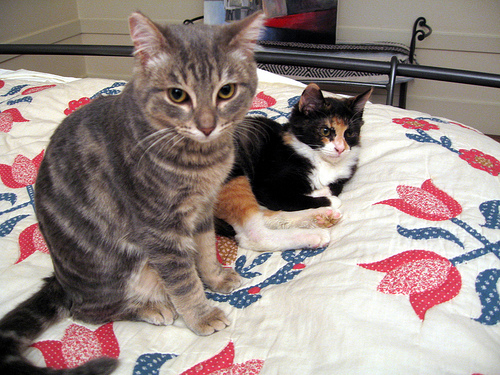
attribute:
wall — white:
[1, 3, 495, 129]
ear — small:
[124, 11, 169, 61]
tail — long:
[1, 274, 121, 375]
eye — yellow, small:
[162, 85, 191, 105]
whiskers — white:
[120, 117, 196, 174]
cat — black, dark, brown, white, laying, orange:
[212, 71, 374, 251]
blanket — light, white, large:
[2, 20, 499, 373]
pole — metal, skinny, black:
[4, 38, 497, 91]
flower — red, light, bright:
[372, 175, 461, 226]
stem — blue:
[392, 225, 465, 247]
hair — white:
[133, 17, 157, 54]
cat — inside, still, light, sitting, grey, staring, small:
[0, 8, 264, 373]